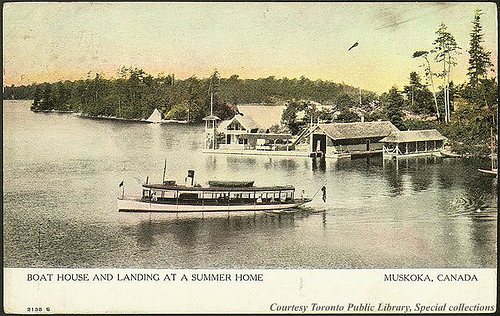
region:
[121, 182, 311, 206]
this is a boat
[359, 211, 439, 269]
this is a water body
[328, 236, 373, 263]
the water is calm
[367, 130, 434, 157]
this is a building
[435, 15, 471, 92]
this is a tree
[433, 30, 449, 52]
the leaves are green in coor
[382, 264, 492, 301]
this is a writing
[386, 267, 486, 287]
the writing is in black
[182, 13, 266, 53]
this is the sky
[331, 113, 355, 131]
this is the roof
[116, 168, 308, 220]
The boat in the water.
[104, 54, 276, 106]
trees by the water.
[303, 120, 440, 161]
Boathouses on the water.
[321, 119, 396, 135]
Roof of the boat house.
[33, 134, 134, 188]
The water is calm.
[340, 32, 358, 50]
Bird flying in the sky.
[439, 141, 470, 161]
Small boat by boathouse.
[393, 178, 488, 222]
Ripples in the water.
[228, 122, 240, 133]
Window on the boathouse.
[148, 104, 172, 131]
Sailboat in the water.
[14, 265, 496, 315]
black lettering on the white card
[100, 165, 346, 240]
a white boat on the water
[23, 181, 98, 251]
calm grey water of the lake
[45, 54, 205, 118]
many trees growing beside the lake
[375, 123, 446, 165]
a boat dock next to the lake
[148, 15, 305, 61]
clear blue skies over the lake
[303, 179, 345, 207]
a flag hanging from the back of the boat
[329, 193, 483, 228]
rippling water from the wake of the boat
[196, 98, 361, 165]
a building next to the lake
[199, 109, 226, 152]
an observation tower next to the building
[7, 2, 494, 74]
light in daytime sky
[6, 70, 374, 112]
line of trees on the horizon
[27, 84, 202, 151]
land on water bank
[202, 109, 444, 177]
buildings overlooking water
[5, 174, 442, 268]
long boat on the water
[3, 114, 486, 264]
body of calm water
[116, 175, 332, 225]
flag on back of boat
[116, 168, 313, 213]
rowboat on top of boat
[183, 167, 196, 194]
smoke stack of boat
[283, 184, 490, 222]
water ripples created by boat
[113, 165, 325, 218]
A boat on the river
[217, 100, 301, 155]
A house on the river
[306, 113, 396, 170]
A boat house on the river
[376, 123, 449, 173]
A pier on the river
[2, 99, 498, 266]
The wide river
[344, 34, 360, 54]
A flying bird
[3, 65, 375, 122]
Woods along the river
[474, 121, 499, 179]
The edge of another boat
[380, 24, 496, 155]
More trees by the river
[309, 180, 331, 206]
A flag hanging from the back of a boat